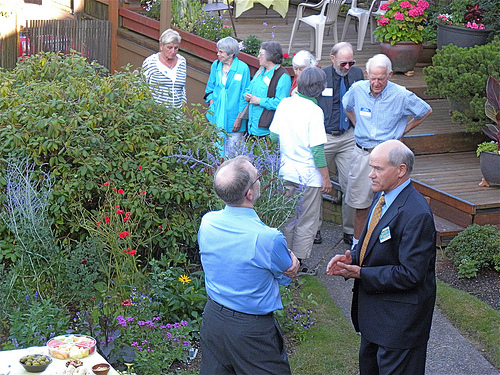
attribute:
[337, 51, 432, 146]
man — older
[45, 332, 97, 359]
container — plastic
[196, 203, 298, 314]
shirt — blue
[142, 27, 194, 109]
senior citizen — in a garden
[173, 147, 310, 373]
senior citizen — in a garden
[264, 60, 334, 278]
senior citizen — in a garden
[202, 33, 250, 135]
senior citizen — in a garden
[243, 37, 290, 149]
senior citizen — in a garden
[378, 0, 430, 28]
flowers — potted, pink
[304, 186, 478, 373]
suit — dark gray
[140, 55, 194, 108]
shirt — striped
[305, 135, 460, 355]
man — balding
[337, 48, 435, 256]
man — white haired, old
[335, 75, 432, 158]
shirt — blue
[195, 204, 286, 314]
shirt — blue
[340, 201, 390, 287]
tie — neck, gold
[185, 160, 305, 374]
man — balding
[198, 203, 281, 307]
shirt — blue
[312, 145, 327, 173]
shirt — white and green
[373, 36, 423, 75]
planter — large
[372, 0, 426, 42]
flowers — big, pink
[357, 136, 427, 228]
man — balding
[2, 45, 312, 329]
shrubs — green, in a garden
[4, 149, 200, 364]
flowers — in a garden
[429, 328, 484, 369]
path — paved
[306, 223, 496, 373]
pathway — gray, paved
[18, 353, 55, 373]
bowl — small, black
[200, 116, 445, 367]
people — elderly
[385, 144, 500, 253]
decking — wooden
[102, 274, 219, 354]
flowers — purple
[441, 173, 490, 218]
deck — wooden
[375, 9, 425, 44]
plant — pink flowered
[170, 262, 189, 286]
flower — yellow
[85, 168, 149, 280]
flowers — red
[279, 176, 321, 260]
pants — dark tan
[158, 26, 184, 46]
gray hair — short